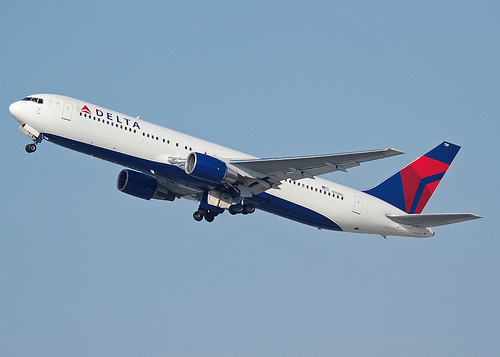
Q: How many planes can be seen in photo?
A: 1.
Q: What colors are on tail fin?
A: Red and blue.